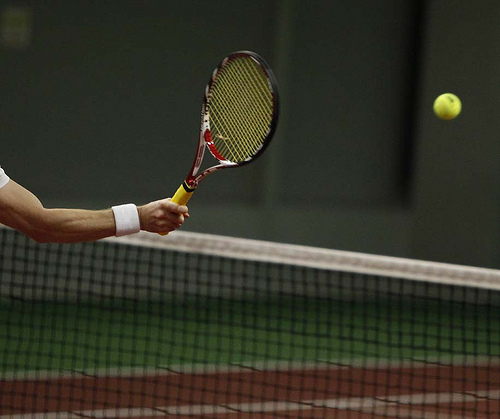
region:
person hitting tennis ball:
[2, 24, 482, 359]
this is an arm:
[6, 42, 294, 312]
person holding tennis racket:
[148, 18, 294, 232]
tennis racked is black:
[159, 21, 302, 225]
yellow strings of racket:
[197, 47, 279, 162]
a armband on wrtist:
[99, 187, 156, 248]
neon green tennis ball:
[434, 82, 471, 127]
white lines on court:
[14, 313, 457, 413]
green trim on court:
[49, 270, 490, 387]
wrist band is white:
[92, 188, 163, 253]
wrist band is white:
[106, 194, 149, 254]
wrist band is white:
[106, 186, 168, 267]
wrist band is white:
[99, 195, 154, 263]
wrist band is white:
[106, 197, 154, 268]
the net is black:
[73, 303, 222, 388]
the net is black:
[126, 295, 288, 384]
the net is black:
[144, 303, 351, 413]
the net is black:
[127, 301, 367, 413]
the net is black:
[129, 294, 279, 372]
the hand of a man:
[118, 167, 217, 246]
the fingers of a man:
[136, 183, 206, 258]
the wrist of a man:
[106, 190, 143, 260]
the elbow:
[18, 214, 73, 264]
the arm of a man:
[18, 170, 217, 267]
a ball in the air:
[376, 71, 491, 158]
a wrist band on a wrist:
[101, 187, 150, 248]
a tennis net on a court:
[110, 180, 458, 388]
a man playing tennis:
[35, 2, 480, 297]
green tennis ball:
[418, 82, 465, 126]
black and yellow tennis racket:
[152, 31, 292, 236]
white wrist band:
[95, 195, 152, 249]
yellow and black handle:
[164, 179, 204, 214]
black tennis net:
[0, 207, 498, 414]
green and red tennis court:
[5, 303, 496, 417]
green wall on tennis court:
[3, 2, 498, 308]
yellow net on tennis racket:
[187, 53, 285, 163]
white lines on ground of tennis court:
[10, 350, 496, 378]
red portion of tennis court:
[7, 366, 497, 413]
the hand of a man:
[116, 170, 217, 261]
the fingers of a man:
[125, 176, 187, 271]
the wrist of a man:
[97, 169, 163, 264]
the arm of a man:
[6, 169, 230, 254]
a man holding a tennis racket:
[159, 53, 306, 248]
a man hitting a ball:
[132, 56, 479, 281]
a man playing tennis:
[33, 81, 306, 284]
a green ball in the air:
[338, 78, 460, 189]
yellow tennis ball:
[423, 87, 464, 124]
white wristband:
[111, 193, 144, 242]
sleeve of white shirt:
[2, 170, 18, 223]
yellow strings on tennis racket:
[204, 50, 275, 167]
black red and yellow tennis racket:
[155, 25, 301, 239]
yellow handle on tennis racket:
[163, 175, 195, 219]